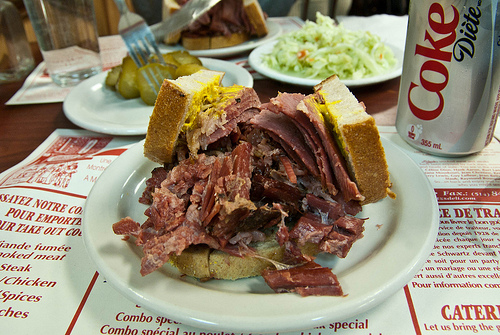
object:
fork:
[111, 0, 172, 96]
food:
[131, 60, 186, 107]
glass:
[22, 0, 103, 88]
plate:
[81, 128, 438, 334]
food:
[110, 74, 385, 297]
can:
[395, 0, 499, 157]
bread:
[143, 68, 225, 166]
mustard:
[186, 75, 247, 126]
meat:
[112, 202, 206, 276]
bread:
[155, 236, 300, 281]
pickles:
[105, 48, 205, 106]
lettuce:
[267, 11, 395, 78]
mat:
[1, 123, 499, 334]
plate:
[246, 34, 404, 87]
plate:
[62, 56, 254, 138]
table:
[1, 36, 499, 333]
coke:
[406, 3, 458, 121]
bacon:
[261, 267, 345, 296]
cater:
[440, 304, 500, 323]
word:
[328, 320, 371, 331]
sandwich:
[161, 0, 269, 51]